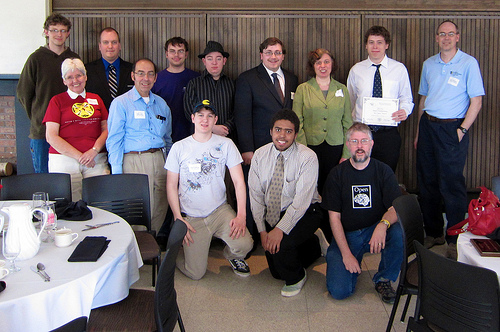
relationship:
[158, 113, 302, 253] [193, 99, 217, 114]
boy wearing baseball hat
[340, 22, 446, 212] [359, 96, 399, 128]
boy holding certificate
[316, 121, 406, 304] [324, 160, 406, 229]
man wearing shirt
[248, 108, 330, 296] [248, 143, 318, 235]
man wearing shirt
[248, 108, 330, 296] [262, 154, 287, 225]
man wearing tie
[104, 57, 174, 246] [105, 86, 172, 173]
man wearing shirt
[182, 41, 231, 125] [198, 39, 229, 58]
boy wearing fedora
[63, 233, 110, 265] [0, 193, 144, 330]
napkin on table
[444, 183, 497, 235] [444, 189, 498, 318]
purse on table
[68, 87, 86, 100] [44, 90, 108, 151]
collar on shirt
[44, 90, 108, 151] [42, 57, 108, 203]
shirt on woman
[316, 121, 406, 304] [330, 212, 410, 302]
man wearing jeans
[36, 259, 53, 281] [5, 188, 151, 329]
spoon on table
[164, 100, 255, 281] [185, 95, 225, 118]
boy wearing cap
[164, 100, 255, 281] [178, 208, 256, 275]
boy wearing pants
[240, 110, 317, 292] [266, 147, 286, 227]
man wearing tie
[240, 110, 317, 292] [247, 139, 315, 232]
man wearing shirt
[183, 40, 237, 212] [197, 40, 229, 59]
boy wearing fedora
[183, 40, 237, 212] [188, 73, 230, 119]
boy wearing shirt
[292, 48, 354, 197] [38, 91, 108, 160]
people wearing shirt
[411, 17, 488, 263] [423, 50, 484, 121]
man wearing shirt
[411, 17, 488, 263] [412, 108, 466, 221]
man wearing pants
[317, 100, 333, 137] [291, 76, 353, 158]
buttons are on blazer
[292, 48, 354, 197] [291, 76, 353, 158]
people wearing blazer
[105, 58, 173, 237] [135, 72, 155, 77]
man wearing eyeglasses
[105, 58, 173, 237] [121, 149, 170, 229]
man wearing pants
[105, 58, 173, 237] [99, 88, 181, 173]
man wearing shirt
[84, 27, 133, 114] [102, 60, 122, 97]
man wearing blue shirt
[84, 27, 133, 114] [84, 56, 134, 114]
man wearing black shirt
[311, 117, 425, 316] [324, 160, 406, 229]
man wearing shirt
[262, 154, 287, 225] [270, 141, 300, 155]
tie on neck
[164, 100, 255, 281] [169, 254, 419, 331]
boy kneeling on floor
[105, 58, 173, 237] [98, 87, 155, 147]
man wearing shirt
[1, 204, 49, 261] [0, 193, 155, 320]
container on table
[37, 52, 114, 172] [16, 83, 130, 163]
woman wearing shirt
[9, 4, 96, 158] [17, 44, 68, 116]
man wearing sweater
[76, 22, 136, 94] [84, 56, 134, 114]
man wearing black shirt